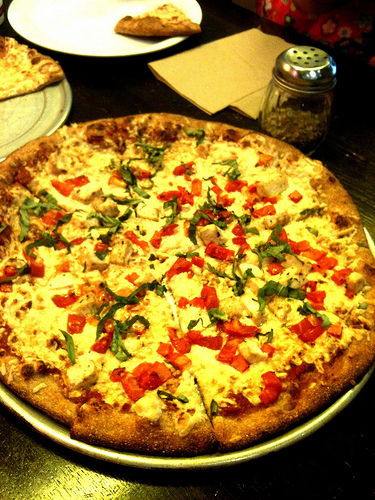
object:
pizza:
[1, 109, 373, 457]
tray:
[0, 222, 375, 470]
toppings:
[7, 146, 151, 223]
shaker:
[258, 45, 337, 158]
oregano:
[257, 301, 306, 341]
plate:
[4, 0, 204, 58]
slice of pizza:
[112, 4, 204, 40]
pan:
[0, 35, 74, 165]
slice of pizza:
[1, 35, 65, 103]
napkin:
[146, 27, 297, 120]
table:
[3, 1, 374, 496]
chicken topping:
[11, 154, 362, 419]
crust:
[2, 111, 374, 457]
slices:
[2, 113, 372, 458]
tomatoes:
[108, 359, 175, 403]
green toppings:
[108, 313, 134, 362]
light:
[19, 461, 141, 500]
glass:
[260, 80, 333, 160]